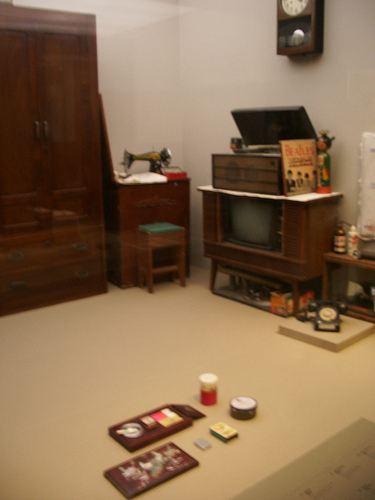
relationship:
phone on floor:
[285, 292, 354, 340] [0, 265, 375, 498]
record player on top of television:
[205, 105, 334, 195] [218, 192, 283, 255]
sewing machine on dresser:
[118, 145, 173, 182] [96, 92, 191, 292]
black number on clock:
[278, 0, 310, 15] [299, 4, 305, 8]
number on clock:
[293, 4, 301, 15] [270, 1, 326, 64]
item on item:
[101, 438, 202, 500] [101, 438, 202, 500]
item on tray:
[101, 438, 202, 500] [102, 402, 199, 452]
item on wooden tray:
[101, 438, 202, 500] [109, 405, 206, 452]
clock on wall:
[270, 1, 326, 64] [183, 1, 363, 116]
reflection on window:
[26, 185, 161, 302] [11, 55, 87, 216]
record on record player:
[278, 133, 323, 189] [210, 104, 320, 197]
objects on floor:
[102, 374, 260, 497] [7, 284, 370, 498]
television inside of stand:
[218, 190, 280, 250] [194, 184, 341, 318]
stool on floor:
[133, 228, 216, 299] [45, 307, 139, 375]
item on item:
[145, 456, 164, 500] [101, 438, 202, 500]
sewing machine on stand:
[118, 145, 173, 176] [112, 170, 199, 292]